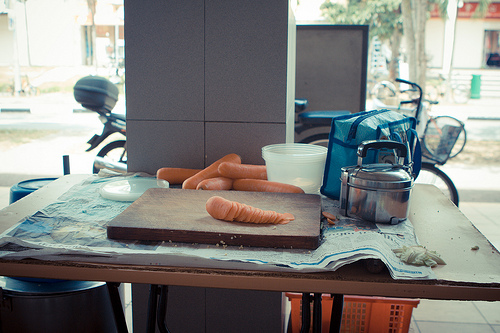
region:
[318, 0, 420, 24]
a green tree.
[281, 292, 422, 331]
a orange crate.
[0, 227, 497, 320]
a big brown table.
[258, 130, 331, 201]
a white container.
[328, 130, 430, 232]
a grey metal tea pot.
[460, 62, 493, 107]
a green garbage can.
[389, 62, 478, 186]
a light grey bicycle.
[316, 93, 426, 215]
a light blue bag.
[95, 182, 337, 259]
a wooden cutting board.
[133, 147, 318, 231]
a table with carrots on top.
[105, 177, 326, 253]
brown wooden cutting board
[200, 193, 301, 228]
chopped orange carrot on board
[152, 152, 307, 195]
bunch of carrots for cutting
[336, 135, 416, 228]
stainless steel tea kettle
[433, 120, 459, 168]
newspaper in bicycle basket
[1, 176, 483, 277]
newspaper covering top of table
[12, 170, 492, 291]
brown wooden table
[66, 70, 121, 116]
black helmet carrier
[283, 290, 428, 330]
bright orange laundry basket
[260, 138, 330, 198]
plastic container for carrots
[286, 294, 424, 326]
the crate is orange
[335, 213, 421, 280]
newspaper is on the table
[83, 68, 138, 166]
bike is parked outside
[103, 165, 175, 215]
the lid is plastic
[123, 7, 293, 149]
the column is grey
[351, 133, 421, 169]
the handle is black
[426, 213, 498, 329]
the table is wooden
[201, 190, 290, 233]
the carrot is cut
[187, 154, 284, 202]
the carrors are red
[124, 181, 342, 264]
the cutting board is brown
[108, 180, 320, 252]
the cutting board is wooden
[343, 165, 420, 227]
the surface is silver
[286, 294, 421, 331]
the basket is orange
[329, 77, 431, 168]
the bag is blue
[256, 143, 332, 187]
the container is clear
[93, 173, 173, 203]
the lid is on the table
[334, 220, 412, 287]
newspaper is on the table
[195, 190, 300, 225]
some sliced up sausage meat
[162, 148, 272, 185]
a pile of sausages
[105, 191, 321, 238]
a large wooden cutting board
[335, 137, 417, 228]
a silver tea pot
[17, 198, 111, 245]
a table cloth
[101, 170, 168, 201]
a small clear plastic lid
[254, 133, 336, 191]
a small clear plastic container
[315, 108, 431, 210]
a small blue backpack bag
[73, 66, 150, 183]
a motorcyle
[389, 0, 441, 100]
a small tree